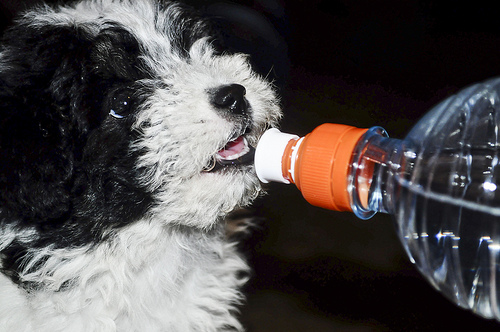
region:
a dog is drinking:
[91, 51, 401, 298]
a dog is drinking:
[141, 14, 331, 224]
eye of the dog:
[93, 86, 150, 127]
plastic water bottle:
[400, 158, 492, 245]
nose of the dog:
[209, 93, 255, 116]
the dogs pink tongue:
[218, 141, 250, 155]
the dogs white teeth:
[228, 152, 240, 158]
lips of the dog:
[234, 154, 251, 164]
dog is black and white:
[17, 36, 269, 284]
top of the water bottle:
[253, 138, 290, 182]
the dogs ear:
[10, 127, 95, 221]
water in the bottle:
[415, 172, 486, 241]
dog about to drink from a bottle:
[5, 5, 496, 321]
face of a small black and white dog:
[0, 0, 272, 225]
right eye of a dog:
[86, 70, 147, 135]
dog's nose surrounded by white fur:
[191, 76, 271, 122]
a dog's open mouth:
[185, 123, 257, 184]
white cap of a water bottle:
[248, 118, 298, 189]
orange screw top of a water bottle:
[290, 112, 360, 217]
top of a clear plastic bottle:
[386, 76, 491, 321]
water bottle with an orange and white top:
[246, 73, 488, 285]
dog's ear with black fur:
[1, 24, 106, 256]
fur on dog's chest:
[223, 247, 260, 326]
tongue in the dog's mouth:
[218, 137, 251, 159]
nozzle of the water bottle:
[246, 113, 298, 193]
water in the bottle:
[391, 180, 481, 221]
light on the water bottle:
[479, 175, 495, 206]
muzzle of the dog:
[163, 66, 283, 149]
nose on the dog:
[193, 77, 258, 137]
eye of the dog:
[88, 72, 147, 156]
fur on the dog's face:
[107, 98, 170, 215]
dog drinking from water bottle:
[69, 15, 311, 253]